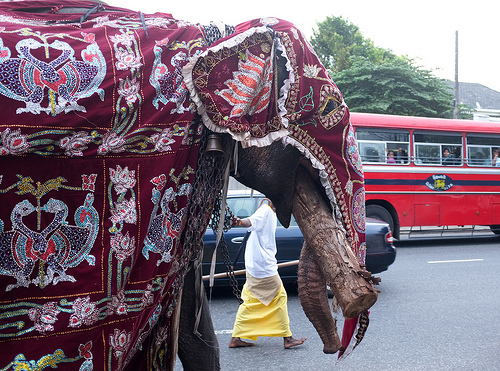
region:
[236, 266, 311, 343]
yellow skirt worn by elephant trainer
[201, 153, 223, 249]
heavy chains worn by elephant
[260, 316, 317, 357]
person walking without shoes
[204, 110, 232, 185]
dark brown bell worn on elephants ear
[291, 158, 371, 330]
large piece of wood carried by elelphant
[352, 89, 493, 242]
red bus used for transportation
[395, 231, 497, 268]
white line drawn in middle of road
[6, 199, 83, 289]
decorative birds sewn into a design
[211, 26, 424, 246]
cloth hood covering elephant's head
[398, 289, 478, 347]
grey asphalt on road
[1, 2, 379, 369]
garishly dressed elephant on city street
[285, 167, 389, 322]
tree trunk carried by elephant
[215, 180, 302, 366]
handler in yellow skirt with white shirt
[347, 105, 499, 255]
red bus with passengers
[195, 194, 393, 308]
dark blue sedan behind elephant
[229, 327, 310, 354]
handler's bare feet on pavement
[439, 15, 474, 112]
light pole above red bus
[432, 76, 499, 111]
mountains in the distance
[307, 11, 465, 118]
green trees behind red bus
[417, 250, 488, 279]
white line in pavement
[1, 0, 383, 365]
large elephant walking down the street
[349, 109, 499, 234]
red bus on street behind elephant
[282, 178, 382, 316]
large wood in mouth of elephant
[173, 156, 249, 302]
chain around neck of elephant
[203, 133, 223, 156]
bell on chain around neck on elephant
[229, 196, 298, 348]
man holding chain on of elephant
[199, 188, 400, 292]
black car behind man with elephant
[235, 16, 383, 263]
hood on elephant head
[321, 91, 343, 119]
eye hole on hood of elephant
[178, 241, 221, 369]
leg of elephant walking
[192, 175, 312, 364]
man is holding a chain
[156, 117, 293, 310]
chain is attached to the elephant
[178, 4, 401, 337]
elephant is wearing a headdress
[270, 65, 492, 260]
the bus is red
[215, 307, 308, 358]
the man is bare foot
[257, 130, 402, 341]
elephant is carrying a tree trunk in his mouth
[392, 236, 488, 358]
the street is grey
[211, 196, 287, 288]
man is wearing a white shirt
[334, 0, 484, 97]
the sky is overcast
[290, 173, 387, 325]
the log is brown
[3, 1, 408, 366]
an elephant that has a cover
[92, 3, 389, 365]
an elephant carrying a log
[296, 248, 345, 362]
the trunk of an elephant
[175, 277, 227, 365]
the leg of an elephant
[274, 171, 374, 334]
a log in an elephants mouth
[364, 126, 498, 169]
the windows of a bus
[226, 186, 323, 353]
a person walking beside an elephant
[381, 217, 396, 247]
the taillight of a car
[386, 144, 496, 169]
people looking out windows on a bus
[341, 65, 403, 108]
the leaves of a tree